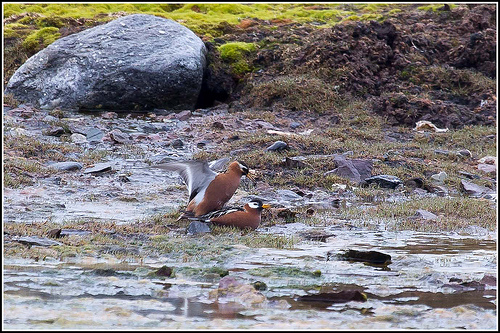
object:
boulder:
[3, 14, 209, 114]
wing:
[154, 159, 219, 198]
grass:
[3, 2, 374, 39]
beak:
[262, 204, 272, 209]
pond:
[0, 231, 498, 333]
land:
[40, 235, 478, 317]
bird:
[150, 157, 255, 223]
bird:
[188, 200, 270, 231]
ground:
[11, 108, 499, 331]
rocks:
[7, 104, 500, 201]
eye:
[253, 203, 259, 206]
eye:
[243, 168, 248, 173]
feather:
[151, 160, 218, 199]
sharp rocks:
[332, 159, 358, 185]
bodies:
[187, 173, 241, 216]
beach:
[0, 110, 500, 252]